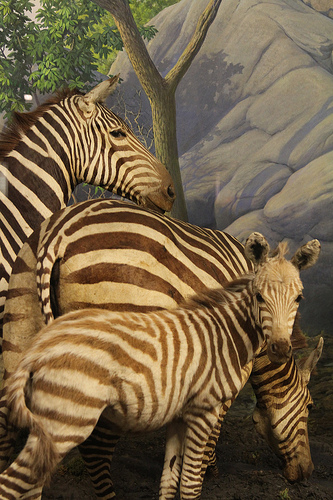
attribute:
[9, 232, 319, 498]
zebra — black, white, looking at camera, animal, here, looking up, stuffed, baby, fake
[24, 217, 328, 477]
zebra — eating, here, looking down, grazing, fake, adult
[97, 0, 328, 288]
mountain — painted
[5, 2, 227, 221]
tree — painted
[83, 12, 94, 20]
leaf — green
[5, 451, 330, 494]
ground — dirt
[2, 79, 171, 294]
zebra — here, looking up, adult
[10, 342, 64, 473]
tail — light, small